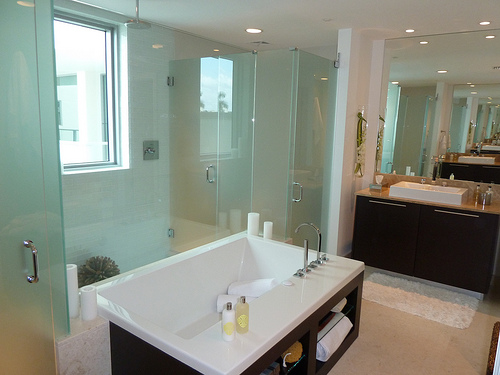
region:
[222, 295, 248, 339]
shampoo and conditioner bottles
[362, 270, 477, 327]
a white rug on the ground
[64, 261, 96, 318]
two white candles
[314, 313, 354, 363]
a rolled up white towel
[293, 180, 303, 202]
shower door handle is metal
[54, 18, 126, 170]
a window inside the shower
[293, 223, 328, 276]
a silver water faucet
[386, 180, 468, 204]
a raised sink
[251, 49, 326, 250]
a glass door on the shower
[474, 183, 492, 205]
bottle sitting next to the sink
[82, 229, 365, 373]
a large square bathtub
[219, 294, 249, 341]
two bottles on the edge of the tub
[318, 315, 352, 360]
a rolled up white towel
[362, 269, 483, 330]
a white fluffy rug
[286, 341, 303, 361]
a yellow sponge for bathing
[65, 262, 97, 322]
stacks of toilet paper rolls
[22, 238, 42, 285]
a silver shower handle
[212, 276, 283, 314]
rolled up white towels in the tub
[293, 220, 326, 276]
a big curved metal bathtub faucet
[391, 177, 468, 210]
a square white sink basin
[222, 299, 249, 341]
Bottles of shampoo and conditioner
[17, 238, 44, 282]
Shiny chrome door handle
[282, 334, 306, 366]
Small washing scrubber in shelf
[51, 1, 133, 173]
Window in bathroom wall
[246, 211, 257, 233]
Large white candle on tub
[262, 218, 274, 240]
Small white candle on tub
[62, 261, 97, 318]
Two candles on tub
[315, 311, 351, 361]
Rolled white towel in shelf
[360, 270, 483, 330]
White bath mat on floor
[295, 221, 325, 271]
Silver water faucets on tub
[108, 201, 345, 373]
this is a bathtub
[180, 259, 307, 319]
towels inside the tub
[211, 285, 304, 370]
bottles of soap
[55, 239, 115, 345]
white candles on the marble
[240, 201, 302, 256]
candles on the side of the tub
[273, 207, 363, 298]
this is the faucet for the tub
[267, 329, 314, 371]
this is a loofah ball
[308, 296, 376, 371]
a towel rolled on the shelf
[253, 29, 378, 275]
a shower door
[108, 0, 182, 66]
an overhead shower faucet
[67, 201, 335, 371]
white tub in bathroom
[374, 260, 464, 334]
white rug on floor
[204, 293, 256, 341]
two bottles on tub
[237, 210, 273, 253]
white candles on tub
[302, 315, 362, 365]
white towel under tub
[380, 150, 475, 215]
white and raised sink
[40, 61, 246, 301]
green door on shower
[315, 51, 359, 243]
white wall in bathroom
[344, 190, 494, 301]
brown drawers on lavatory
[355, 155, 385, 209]
grey box of tissues